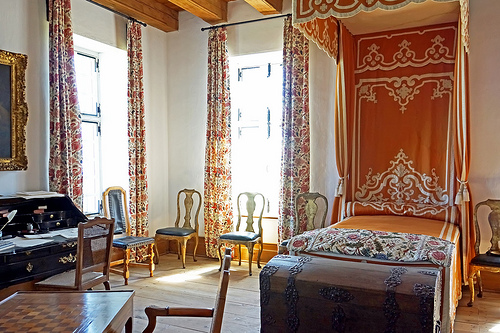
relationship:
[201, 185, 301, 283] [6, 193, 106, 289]
chair in front of desk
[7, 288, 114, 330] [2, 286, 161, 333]
chess on table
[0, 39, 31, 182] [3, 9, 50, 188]
framed picture on wall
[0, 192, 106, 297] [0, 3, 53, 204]
desk against wall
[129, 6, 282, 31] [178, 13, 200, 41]
beams on ceiling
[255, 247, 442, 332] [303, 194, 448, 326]
trunk at foot of bed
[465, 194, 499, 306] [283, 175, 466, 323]
chair next to bed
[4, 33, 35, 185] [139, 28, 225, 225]
painting hanging on wall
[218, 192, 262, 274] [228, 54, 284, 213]
chair next to window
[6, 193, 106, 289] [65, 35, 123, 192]
desk next to window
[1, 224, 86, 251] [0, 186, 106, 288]
paper on desk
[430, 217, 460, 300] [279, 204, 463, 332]
edge of a bed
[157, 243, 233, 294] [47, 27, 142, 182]
sunshine through a window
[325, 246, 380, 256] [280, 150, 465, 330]
edge of a bed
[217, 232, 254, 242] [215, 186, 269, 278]
chair edge of a chair